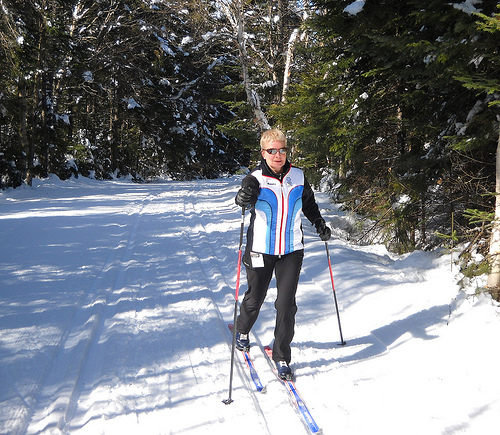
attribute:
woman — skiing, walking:
[231, 124, 335, 382]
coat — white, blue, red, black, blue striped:
[235, 160, 327, 262]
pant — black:
[232, 244, 304, 365]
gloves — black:
[315, 219, 333, 242]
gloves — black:
[233, 187, 251, 210]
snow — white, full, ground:
[1, 174, 499, 435]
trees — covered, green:
[1, 1, 499, 289]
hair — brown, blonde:
[254, 127, 288, 150]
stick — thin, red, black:
[321, 232, 351, 345]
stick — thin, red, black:
[223, 204, 247, 400]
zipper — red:
[275, 185, 286, 261]